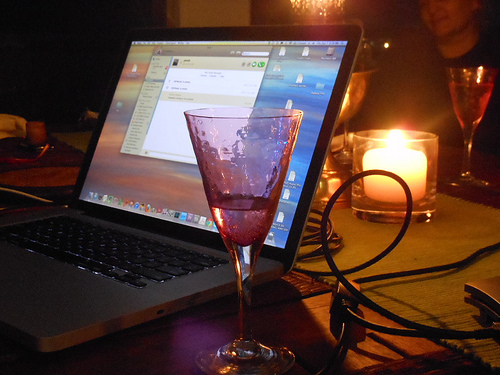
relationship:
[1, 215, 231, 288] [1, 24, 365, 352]
keyboard on laptop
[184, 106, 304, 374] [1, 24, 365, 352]
glass next to laptop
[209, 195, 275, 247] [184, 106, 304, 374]
liquid in glass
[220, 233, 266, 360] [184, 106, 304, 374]
stem of glass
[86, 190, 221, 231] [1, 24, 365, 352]
icons on laptop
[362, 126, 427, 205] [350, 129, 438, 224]
candle in glass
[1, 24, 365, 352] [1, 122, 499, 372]
laptop on table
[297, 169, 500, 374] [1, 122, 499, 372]
cord on table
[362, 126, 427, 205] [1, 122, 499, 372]
candle on table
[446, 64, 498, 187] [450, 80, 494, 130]
glass has wine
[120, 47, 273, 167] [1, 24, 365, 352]
window on laptop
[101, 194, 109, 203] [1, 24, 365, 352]
icon on laptop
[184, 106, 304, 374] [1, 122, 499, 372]
glass on table